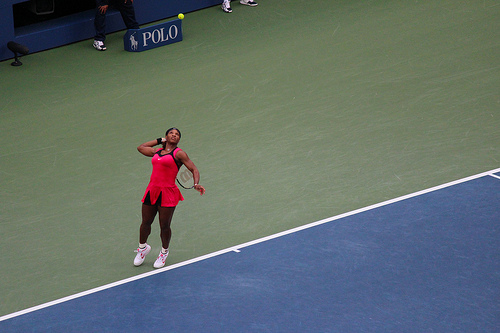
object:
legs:
[139, 205, 158, 244]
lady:
[133, 126, 207, 270]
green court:
[0, 0, 500, 318]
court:
[0, 0, 498, 333]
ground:
[2, 2, 497, 331]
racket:
[176, 164, 194, 190]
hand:
[193, 184, 206, 196]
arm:
[180, 152, 201, 185]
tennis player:
[133, 126, 206, 269]